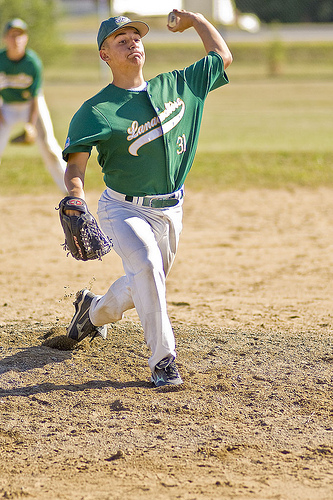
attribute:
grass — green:
[235, 148, 303, 172]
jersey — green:
[59, 83, 259, 198]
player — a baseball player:
[58, 8, 232, 387]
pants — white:
[23, 164, 265, 408]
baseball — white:
[166, 5, 181, 34]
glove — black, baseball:
[59, 186, 110, 264]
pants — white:
[88, 185, 186, 368]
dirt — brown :
[0, 190, 331, 498]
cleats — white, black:
[66, 285, 187, 389]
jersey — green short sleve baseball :
[41, 48, 250, 209]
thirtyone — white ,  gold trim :
[175, 130, 190, 157]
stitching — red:
[167, 14, 180, 23]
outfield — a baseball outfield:
[9, 32, 323, 151]